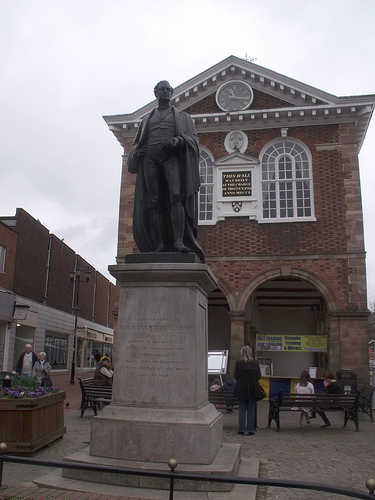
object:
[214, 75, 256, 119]
clock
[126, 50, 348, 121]
roof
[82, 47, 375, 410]
building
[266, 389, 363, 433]
bench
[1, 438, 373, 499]
railing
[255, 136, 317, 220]
window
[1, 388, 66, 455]
container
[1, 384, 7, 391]
flowers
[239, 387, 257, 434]
jeans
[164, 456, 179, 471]
top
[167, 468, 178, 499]
post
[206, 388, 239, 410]
bench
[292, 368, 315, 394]
people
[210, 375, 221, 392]
people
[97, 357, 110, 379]
people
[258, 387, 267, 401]
black purse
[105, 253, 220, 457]
monument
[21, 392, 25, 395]
flower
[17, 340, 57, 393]
couple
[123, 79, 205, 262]
statue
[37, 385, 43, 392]
flowers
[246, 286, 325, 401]
alcove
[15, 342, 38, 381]
man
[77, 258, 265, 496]
pedestal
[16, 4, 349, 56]
sky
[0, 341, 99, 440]
street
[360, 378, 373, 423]
bench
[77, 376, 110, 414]
bench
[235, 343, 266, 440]
woman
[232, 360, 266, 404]
black jacket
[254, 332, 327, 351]
banner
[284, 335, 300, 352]
writing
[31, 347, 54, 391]
woman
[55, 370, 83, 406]
sidewalk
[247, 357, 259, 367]
shoulder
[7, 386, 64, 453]
bed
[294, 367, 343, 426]
couple